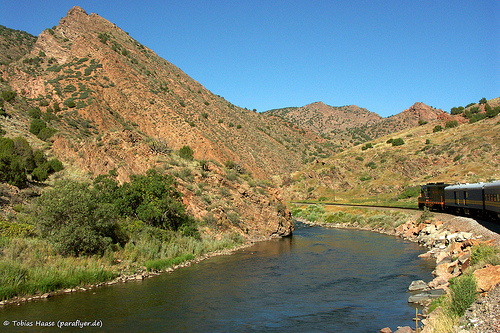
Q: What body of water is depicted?
A: A river.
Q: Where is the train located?
A: To the right of the river.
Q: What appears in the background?
A: Mountains.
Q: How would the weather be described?
A: Sunny, clear, and bright.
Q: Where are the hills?
A: Next to river.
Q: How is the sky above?
A: Clear.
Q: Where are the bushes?
A: Bottom.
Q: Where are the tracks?
A: Between hills.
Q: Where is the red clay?
A: Hills.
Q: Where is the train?
A: On tracks.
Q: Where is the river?
A: Next to hills.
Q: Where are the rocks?
A: Along river.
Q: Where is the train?
A: A valley.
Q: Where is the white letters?
A: Bottom of picture.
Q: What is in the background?
A: Tall pointed mountains.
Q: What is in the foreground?
A: The river.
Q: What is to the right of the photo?
A: A train.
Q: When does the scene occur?
A: Daytime.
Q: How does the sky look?
A: Very blue.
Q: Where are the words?
A: Bottom left of picture.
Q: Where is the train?
A: To the right.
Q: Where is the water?
A: To the left of the train.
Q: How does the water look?
A: Very calm.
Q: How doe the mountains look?
A: Mostly brown.